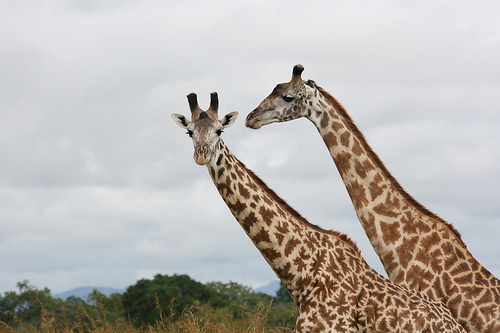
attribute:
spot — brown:
[403, 258, 433, 293]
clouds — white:
[27, 166, 202, 256]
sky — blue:
[18, 8, 496, 273]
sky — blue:
[0, 0, 498, 331]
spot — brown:
[237, 180, 247, 195]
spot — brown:
[249, 227, 275, 250]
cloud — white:
[7, 178, 172, 233]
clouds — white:
[2, 0, 499, 294]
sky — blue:
[60, 44, 153, 221]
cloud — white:
[25, 20, 166, 220]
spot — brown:
[258, 204, 281, 228]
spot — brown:
[393, 237, 422, 262]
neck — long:
[205, 145, 358, 293]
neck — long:
[312, 92, 462, 279]